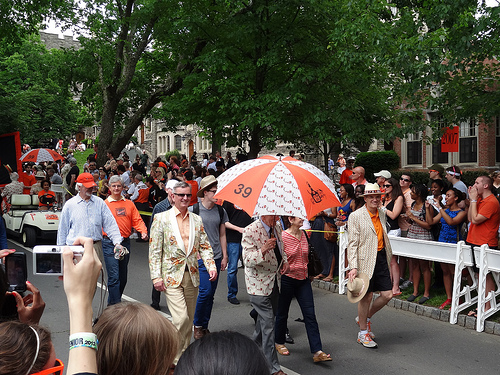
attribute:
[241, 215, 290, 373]
man — walking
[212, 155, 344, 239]
umbrella — red, white, orange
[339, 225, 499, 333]
barricade — white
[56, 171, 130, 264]
man — walking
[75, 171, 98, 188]
cap — orange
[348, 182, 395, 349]
man — walking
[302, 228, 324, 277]
purse — black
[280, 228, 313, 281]
shirt — red, white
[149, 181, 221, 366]
man — walking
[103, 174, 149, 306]
man — walking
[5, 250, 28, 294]
smartphone — black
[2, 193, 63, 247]
golf cart — white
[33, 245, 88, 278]
camera — silver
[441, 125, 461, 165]
sign — orange